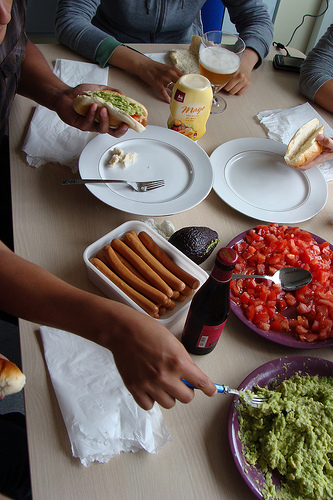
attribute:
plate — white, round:
[74, 120, 211, 217]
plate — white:
[204, 136, 330, 230]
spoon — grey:
[226, 262, 316, 296]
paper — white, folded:
[19, 55, 111, 176]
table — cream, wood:
[4, 36, 332, 500]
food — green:
[233, 373, 332, 495]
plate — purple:
[225, 349, 332, 500]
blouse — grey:
[49, 1, 278, 65]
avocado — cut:
[169, 221, 227, 266]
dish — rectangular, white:
[68, 217, 218, 349]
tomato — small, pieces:
[231, 221, 333, 343]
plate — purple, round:
[215, 222, 331, 352]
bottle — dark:
[180, 240, 242, 357]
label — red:
[194, 317, 228, 355]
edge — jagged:
[23, 149, 87, 176]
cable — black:
[272, 1, 332, 52]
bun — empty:
[281, 115, 331, 171]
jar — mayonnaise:
[163, 72, 217, 156]